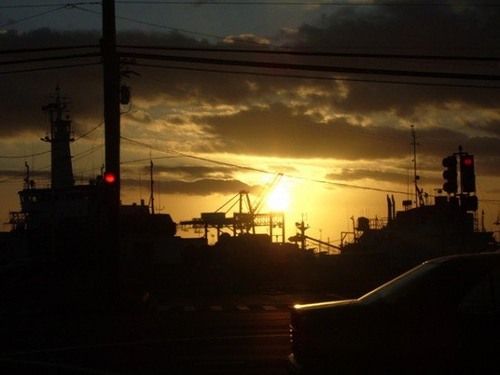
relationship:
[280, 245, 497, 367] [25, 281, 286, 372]
car on street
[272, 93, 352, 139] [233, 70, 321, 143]
clouds in sky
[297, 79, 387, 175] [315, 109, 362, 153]
clouds in sky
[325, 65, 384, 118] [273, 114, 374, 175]
clouds in sky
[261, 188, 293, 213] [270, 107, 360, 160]
sun in sky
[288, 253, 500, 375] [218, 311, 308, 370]
car on road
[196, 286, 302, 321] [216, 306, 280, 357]
lines in road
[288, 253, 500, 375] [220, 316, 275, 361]
car on road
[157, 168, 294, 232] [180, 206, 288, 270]
crane behind car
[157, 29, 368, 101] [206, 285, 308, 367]
lines above roads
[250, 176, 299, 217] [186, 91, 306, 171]
sun in sky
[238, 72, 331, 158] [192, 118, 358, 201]
clouds in sky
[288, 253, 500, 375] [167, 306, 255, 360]
car on street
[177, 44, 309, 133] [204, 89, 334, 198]
clouds in sky